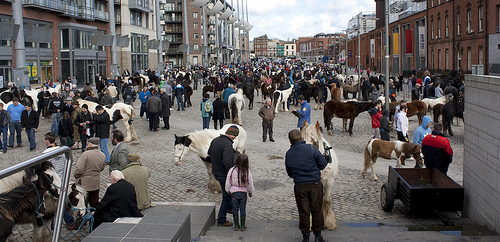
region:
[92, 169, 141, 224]
Man sitting down on a step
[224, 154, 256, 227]
Little girl wearing pink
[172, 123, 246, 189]
White and black horse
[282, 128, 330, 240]
Man wearing a blue jacket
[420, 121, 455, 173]
man wearing a red and black jacket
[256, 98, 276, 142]
Man wearing a tan jacket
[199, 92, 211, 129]
Person wearing a blue jacket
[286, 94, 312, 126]
Man wearing a sky colored jacket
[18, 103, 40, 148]
Man walking on the street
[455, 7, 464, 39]
A window on a building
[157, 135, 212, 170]
a horse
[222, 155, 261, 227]
a girl standing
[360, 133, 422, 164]
a brown and white horse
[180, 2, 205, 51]
a building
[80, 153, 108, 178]
a brown jacket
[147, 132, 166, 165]
the ground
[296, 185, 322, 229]
the person is wearing brown pants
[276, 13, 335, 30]
the white clouds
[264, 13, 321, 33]
clouds in the sky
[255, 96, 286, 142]
a man standing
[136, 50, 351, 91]
people in a crowd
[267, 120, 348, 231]
person standing in front of a course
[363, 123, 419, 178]
small white and brown pony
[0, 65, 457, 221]
bricks laid in the ground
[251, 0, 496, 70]
brick building lining the streets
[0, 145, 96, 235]
a white and black horse tied up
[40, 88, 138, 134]
people standing around a horse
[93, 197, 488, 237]
people standing on stone steps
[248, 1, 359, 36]
blue sky and white clouds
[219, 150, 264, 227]
little girl looking at man standing next to a pony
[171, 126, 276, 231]
Man and a little girl looks after a horse.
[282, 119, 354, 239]
The man takes care of his horse.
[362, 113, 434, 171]
The man walks his pony away.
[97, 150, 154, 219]
The men sit and watch.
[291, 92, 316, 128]
The man checks off horses.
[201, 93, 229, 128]
The couple look at the white horse.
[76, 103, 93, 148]
The lady walks away.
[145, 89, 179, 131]
The group talks among themselves.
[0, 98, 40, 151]
The men walk to see what else there is.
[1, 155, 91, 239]
The horses wait.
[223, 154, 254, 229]
little girl with long brown hair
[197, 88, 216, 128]
woman with teal and black jacket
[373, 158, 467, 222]
wooden horse cart painted black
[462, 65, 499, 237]
grey cement wall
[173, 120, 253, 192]
white and black horse with bridle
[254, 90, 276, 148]
older gentleman with brown jacket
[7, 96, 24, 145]
man with bright blue shirt and blue jeans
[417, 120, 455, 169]
heavy set man with red and black jacket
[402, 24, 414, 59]
bright red flag hanging on building